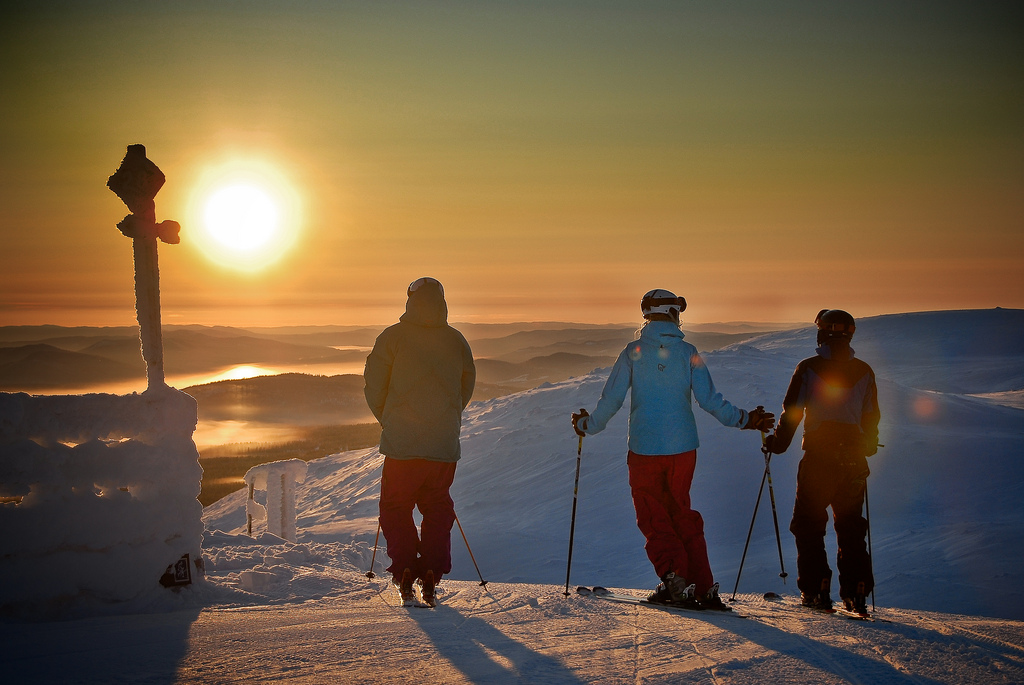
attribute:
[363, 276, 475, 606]
person — standing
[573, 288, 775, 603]
person — standing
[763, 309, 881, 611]
person — standing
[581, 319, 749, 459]
coat — blue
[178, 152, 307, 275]
sun — setting, glowing, orange, yellow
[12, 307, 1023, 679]
snow — white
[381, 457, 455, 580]
pants — red, black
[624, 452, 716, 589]
pants — red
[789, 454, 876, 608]
pants — black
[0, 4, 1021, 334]
sky — clear